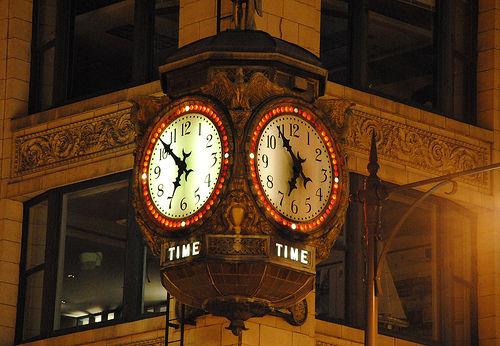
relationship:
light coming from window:
[62, 281, 168, 328] [13, 166, 168, 344]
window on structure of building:
[13, 166, 168, 344] [1, 1, 499, 344]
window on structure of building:
[26, 0, 179, 109] [1, 1, 499, 344]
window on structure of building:
[314, 0, 484, 130] [1, 1, 499, 344]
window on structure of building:
[312, 168, 480, 345] [1, 1, 499, 344]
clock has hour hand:
[135, 96, 236, 232] [170, 149, 193, 199]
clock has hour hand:
[241, 93, 344, 238] [281, 151, 307, 194]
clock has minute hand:
[135, 96, 236, 232] [157, 135, 193, 181]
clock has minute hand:
[241, 93, 344, 238] [271, 123, 313, 188]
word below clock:
[167, 238, 202, 263] [135, 96, 236, 232]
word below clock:
[274, 238, 310, 267] [241, 93, 344, 238]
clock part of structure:
[135, 96, 236, 232] [130, 28, 355, 337]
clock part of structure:
[241, 93, 344, 238] [130, 28, 355, 337]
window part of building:
[13, 166, 168, 344] [1, 1, 499, 344]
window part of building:
[26, 0, 179, 109] [1, 1, 499, 344]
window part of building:
[314, 0, 484, 130] [1, 1, 499, 344]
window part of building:
[312, 168, 480, 345] [1, 1, 499, 344]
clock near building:
[135, 96, 236, 232] [1, 1, 499, 344]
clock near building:
[241, 93, 344, 238] [1, 1, 499, 344]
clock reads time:
[135, 96, 236, 232] [157, 134, 194, 201]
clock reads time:
[241, 93, 344, 238] [272, 124, 311, 196]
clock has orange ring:
[135, 96, 236, 232] [143, 100, 231, 228]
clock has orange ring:
[241, 93, 344, 238] [250, 103, 340, 230]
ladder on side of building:
[157, 283, 187, 345] [1, 1, 499, 344]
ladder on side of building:
[213, 1, 240, 34] [1, 1, 499, 344]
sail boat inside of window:
[373, 234, 409, 330] [312, 168, 480, 345]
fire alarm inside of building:
[78, 248, 107, 271] [1, 1, 499, 344]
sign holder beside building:
[353, 123, 497, 345] [1, 1, 499, 344]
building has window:
[1, 1, 499, 344] [26, 0, 179, 109]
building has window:
[1, 1, 499, 344] [13, 166, 168, 344]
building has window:
[1, 1, 499, 344] [314, 0, 484, 130]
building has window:
[1, 1, 499, 344] [312, 168, 480, 345]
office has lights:
[26, 182, 168, 340] [62, 281, 168, 328]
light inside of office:
[62, 281, 168, 328] [26, 182, 168, 340]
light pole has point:
[353, 123, 497, 345] [360, 126, 383, 181]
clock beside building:
[135, 96, 236, 232] [1, 1, 499, 344]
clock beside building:
[241, 93, 344, 238] [1, 1, 499, 344]